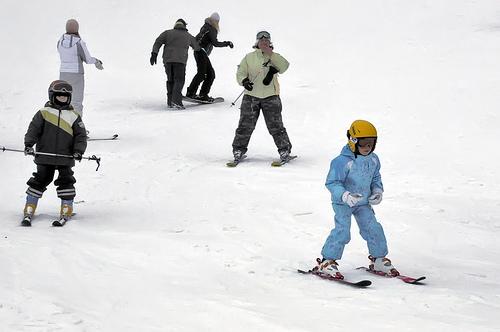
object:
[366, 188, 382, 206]
glove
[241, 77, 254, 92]
glove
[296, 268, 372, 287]
skis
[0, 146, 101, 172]
pole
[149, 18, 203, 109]
people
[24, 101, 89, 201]
snow suit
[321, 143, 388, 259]
snow suit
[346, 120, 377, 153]
helmet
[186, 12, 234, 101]
person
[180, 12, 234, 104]
snowboarder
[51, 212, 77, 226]
skis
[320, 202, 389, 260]
pants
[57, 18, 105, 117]
girl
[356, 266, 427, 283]
skis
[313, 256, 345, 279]
ski boots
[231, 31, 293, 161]
people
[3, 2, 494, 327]
slope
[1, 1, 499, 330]
snow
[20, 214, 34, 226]
skis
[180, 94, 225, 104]
snowboard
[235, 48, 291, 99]
jacket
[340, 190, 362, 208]
glove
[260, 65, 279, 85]
glove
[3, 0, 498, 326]
downhill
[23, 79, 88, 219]
boy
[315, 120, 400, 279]
boy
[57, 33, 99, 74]
jacket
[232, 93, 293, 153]
pants